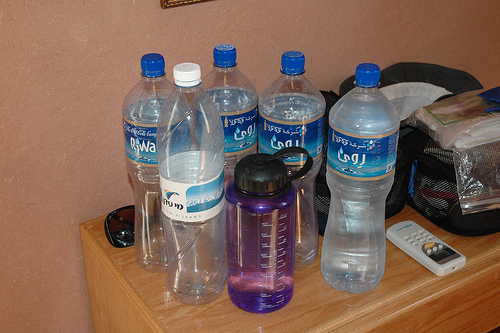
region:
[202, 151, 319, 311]
a purple plastic container.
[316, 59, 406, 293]
a bottle of bottled water.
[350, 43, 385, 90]
a blue plastic bottle lid.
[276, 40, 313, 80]
A blue plastic bottle top.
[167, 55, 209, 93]
a white plastic bottle top.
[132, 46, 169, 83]
a blue plastic bottle top.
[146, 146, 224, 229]
a plastic container label.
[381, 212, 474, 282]
a remote control on a table.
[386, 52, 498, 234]
a metallic object.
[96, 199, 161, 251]
a black plastic object.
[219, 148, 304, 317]
purple water bottle with black lid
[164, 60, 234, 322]
plastic water bottle with white top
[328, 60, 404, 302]
plastic water bottle with blue top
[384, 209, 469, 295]
white remote control with orange button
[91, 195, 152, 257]
a pair of black sunglasses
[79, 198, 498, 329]
wooden desk with items on top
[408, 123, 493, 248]
black mesh bag with items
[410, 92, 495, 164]
white plastic rain poncho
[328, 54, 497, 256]
clothes for the trip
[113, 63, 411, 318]
five bottles of water to drink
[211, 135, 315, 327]
purple reuseable water bottle with black lid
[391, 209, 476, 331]
small white remote control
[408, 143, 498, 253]
mesh netting inside bag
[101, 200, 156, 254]
edge of black sun glasses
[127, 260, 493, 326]
light brown wooden table top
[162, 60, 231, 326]
clear water bottle with white lid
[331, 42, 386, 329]
clear water bottle with blue lid and wrapper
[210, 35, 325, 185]
clear water bottle with blue lid and wrapper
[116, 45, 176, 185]
clear water bottle with blue lid and wrapper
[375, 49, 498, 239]
blak and clear travel bag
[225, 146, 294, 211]
bottle has black lid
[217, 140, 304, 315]
bottle has black lid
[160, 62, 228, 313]
the bottle is empty